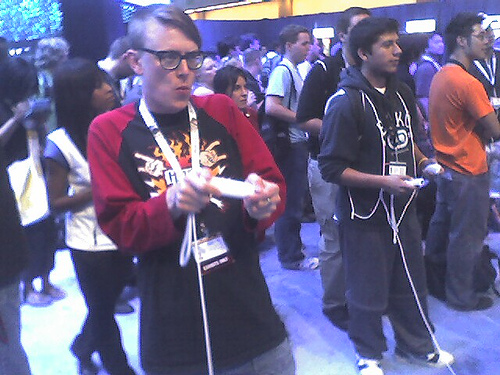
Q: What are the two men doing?
A: Playing wii.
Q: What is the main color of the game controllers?
A: White.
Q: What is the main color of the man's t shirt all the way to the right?
A: ORange.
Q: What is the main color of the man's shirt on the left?
A: Red and black.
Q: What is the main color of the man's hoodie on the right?
A: Black and white.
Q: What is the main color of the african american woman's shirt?
A: White.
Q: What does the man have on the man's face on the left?
A: Glasses.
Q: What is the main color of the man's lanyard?
A: White.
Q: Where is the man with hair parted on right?
A: Closest to camera.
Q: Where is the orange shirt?
A: Right.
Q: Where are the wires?
A: On controllers.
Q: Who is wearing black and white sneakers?
A: Man in black hoodie.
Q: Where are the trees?
A: Background.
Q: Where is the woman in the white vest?
A: Behind closest man in glasses.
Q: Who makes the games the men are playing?
A: Wii.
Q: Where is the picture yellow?
A: Top.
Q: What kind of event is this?
A: Gamer.